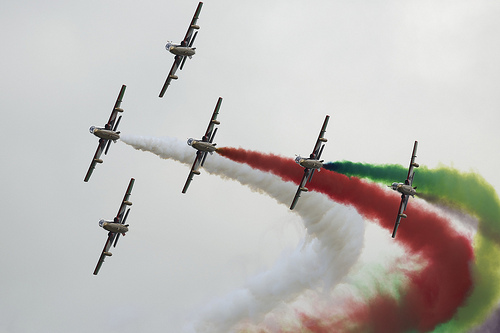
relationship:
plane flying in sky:
[84, 84, 126, 184] [1, 1, 499, 333]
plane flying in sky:
[158, 2, 203, 99] [1, 1, 499, 333]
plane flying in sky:
[93, 176, 135, 276] [1, 1, 499, 333]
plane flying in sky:
[180, 95, 224, 195] [1, 1, 499, 333]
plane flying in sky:
[289, 115, 331, 212] [1, 1, 499, 333]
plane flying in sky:
[390, 141, 419, 239] [1, 1, 499, 333]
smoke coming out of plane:
[322, 162, 499, 332] [289, 115, 331, 212]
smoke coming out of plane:
[116, 134, 500, 333] [180, 95, 224, 195]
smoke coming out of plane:
[116, 134, 500, 333] [84, 84, 126, 184]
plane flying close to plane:
[84, 84, 126, 184] [93, 176, 135, 276]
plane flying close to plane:
[158, 2, 203, 99] [180, 95, 224, 195]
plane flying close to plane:
[289, 115, 331, 212] [390, 141, 419, 239]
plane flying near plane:
[158, 2, 203, 99] [180, 95, 224, 195]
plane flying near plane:
[84, 84, 126, 184] [93, 176, 135, 276]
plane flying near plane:
[289, 115, 331, 212] [390, 141, 419, 239]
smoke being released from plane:
[116, 134, 500, 333] [84, 84, 126, 184]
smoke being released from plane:
[116, 134, 500, 333] [180, 95, 224, 195]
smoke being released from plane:
[322, 162, 499, 332] [289, 115, 331, 212]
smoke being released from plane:
[416, 192, 499, 332] [390, 141, 419, 239]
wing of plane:
[104, 84, 126, 131] [84, 84, 126, 184]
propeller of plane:
[164, 41, 172, 54] [158, 2, 203, 99]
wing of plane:
[84, 138, 108, 182] [84, 84, 126, 184]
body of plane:
[103, 223, 129, 234] [93, 176, 135, 276]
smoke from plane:
[116, 134, 500, 333] [84, 84, 126, 184]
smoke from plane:
[116, 134, 500, 333] [180, 95, 224, 195]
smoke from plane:
[322, 162, 499, 332] [289, 115, 331, 212]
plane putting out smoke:
[84, 84, 126, 184] [116, 134, 500, 333]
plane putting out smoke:
[180, 95, 224, 195] [116, 134, 500, 333]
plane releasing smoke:
[84, 84, 126, 184] [116, 134, 500, 333]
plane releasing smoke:
[180, 95, 224, 195] [116, 134, 500, 333]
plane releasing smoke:
[289, 115, 331, 212] [322, 162, 499, 332]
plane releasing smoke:
[390, 141, 419, 239] [416, 192, 499, 332]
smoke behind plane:
[116, 134, 500, 333] [180, 95, 224, 195]